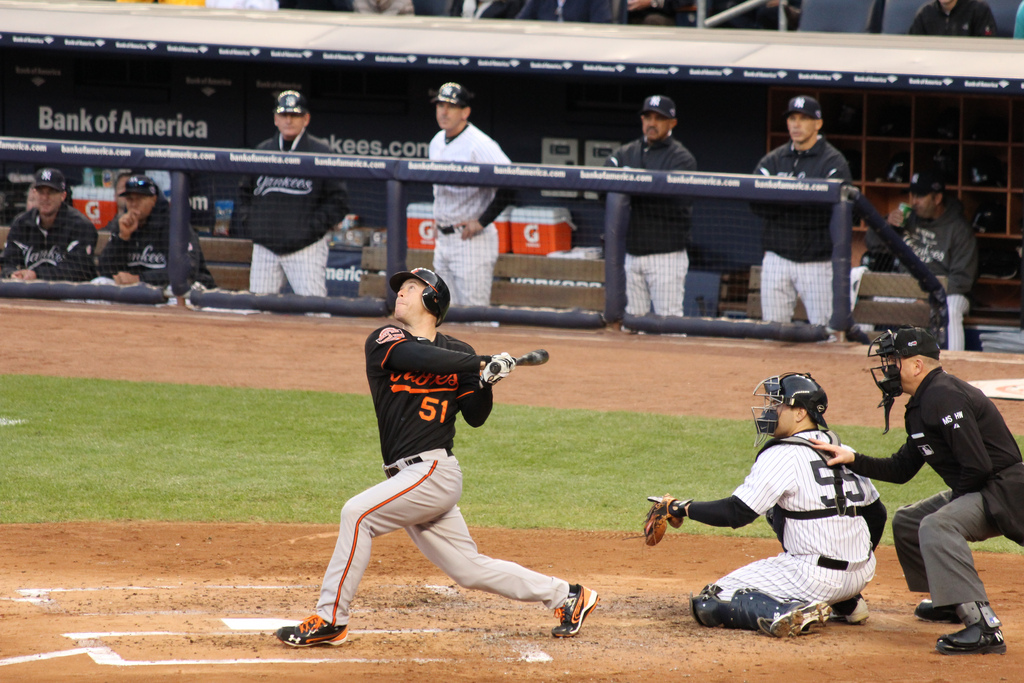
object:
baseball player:
[271, 266, 605, 648]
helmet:
[389, 267, 450, 328]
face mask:
[750, 375, 785, 449]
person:
[424, 81, 512, 307]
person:
[0, 166, 101, 282]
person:
[230, 90, 352, 318]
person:
[746, 94, 854, 325]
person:
[758, 91, 846, 336]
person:
[849, 171, 981, 318]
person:
[88, 174, 217, 289]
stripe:
[330, 457, 441, 627]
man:
[807, 323, 1024, 656]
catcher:
[640, 371, 890, 640]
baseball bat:
[488, 349, 549, 376]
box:
[0, 625, 559, 666]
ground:
[2, 296, 1023, 678]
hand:
[477, 351, 516, 370]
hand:
[480, 351, 515, 388]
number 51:
[417, 395, 449, 424]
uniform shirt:
[362, 322, 495, 467]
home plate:
[217, 617, 304, 631]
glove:
[641, 491, 696, 547]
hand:
[810, 437, 857, 467]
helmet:
[751, 370, 834, 448]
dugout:
[2, 3, 1023, 356]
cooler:
[509, 204, 578, 257]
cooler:
[490, 204, 514, 254]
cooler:
[406, 201, 442, 250]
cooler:
[69, 184, 118, 231]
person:
[599, 95, 702, 339]